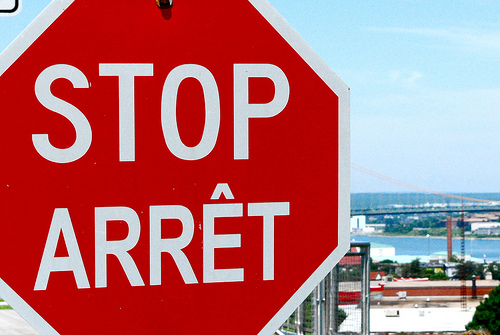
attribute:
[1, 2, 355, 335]
sign — large, red, 8 sides, stop, white, bordered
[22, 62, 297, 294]
letters — white, large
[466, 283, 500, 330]
tree top — green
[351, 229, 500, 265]
water — blue, wide, background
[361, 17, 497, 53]
clouds — white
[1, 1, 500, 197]
sky — blue, clear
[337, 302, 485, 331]
roof — light colored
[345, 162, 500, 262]
bridge — high, suspension, tall, background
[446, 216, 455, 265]
columns — tall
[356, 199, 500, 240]
buildings — background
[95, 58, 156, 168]
t — letter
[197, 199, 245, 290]
e — letter